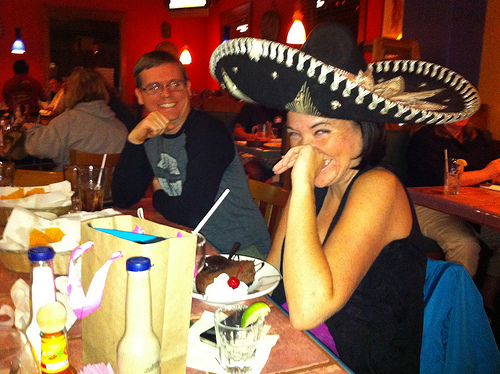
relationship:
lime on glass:
[240, 302, 270, 326] [214, 304, 265, 374]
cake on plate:
[196, 258, 256, 294] [192, 252, 281, 306]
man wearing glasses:
[110, 51, 272, 261] [138, 80, 187, 94]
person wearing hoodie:
[22, 68, 128, 170] [23, 100, 127, 170]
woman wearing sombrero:
[264, 110, 426, 373] [209, 21, 481, 123]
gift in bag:
[90, 225, 168, 248] [81, 215, 197, 373]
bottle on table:
[36, 303, 69, 374] [0, 197, 357, 374]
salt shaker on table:
[27, 247, 57, 363] [0, 197, 357, 374]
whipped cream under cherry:
[202, 273, 249, 305] [229, 269, 246, 288]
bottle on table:
[36, 302, 77, 374] [0, 197, 357, 374]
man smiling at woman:
[110, 51, 272, 261] [264, 110, 426, 373]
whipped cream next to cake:
[202, 273, 249, 305] [196, 258, 256, 294]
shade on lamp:
[12, 39, 25, 54] [11, 4, 27, 55]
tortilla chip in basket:
[30, 227, 51, 246] [1, 238, 73, 277]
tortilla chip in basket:
[45, 226, 65, 243] [1, 238, 73, 277]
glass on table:
[214, 304, 265, 374] [0, 197, 357, 374]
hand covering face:
[271, 144, 326, 178] [286, 113, 348, 188]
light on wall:
[221, 38, 227, 42] [208, 1, 499, 138]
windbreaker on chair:
[424, 259, 499, 373] [425, 258, 467, 374]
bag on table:
[81, 215, 197, 373] [0, 197, 357, 374]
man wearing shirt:
[110, 51, 272, 261] [110, 108, 271, 255]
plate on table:
[192, 252, 281, 306] [0, 197, 357, 374]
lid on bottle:
[126, 257, 151, 270] [36, 303, 69, 374]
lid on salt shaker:
[126, 257, 151, 270] [27, 247, 57, 363]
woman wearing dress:
[264, 110, 426, 373] [322, 167, 423, 373]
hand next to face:
[271, 144, 326, 178] [286, 113, 348, 188]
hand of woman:
[271, 144, 326, 178] [264, 110, 426, 373]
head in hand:
[132, 51, 192, 125] [135, 109, 176, 140]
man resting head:
[110, 51, 272, 261] [132, 51, 192, 125]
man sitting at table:
[110, 51, 272, 261] [0, 197, 357, 374]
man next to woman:
[110, 51, 272, 261] [264, 110, 426, 373]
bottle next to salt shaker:
[36, 303, 69, 374] [27, 247, 57, 363]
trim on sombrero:
[208, 36, 480, 126] [209, 21, 481, 123]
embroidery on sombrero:
[284, 81, 322, 117] [209, 21, 481, 123]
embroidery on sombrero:
[219, 66, 256, 104] [209, 21, 481, 123]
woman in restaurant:
[264, 110, 426, 373] [1, 2, 499, 373]